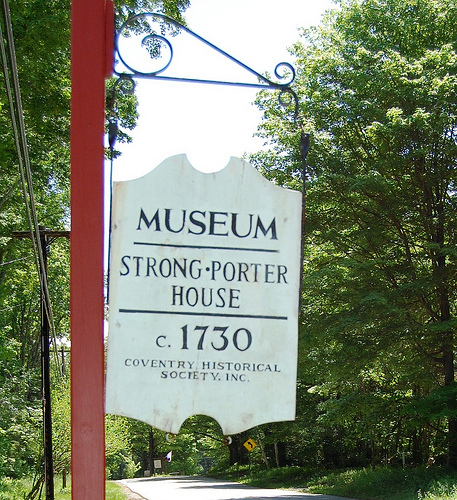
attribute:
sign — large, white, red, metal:
[110, 154, 305, 436]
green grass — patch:
[235, 451, 440, 498]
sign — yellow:
[244, 438, 258, 453]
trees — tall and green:
[257, 1, 455, 468]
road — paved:
[116, 468, 369, 498]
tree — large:
[303, 54, 456, 332]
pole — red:
[70, 1, 117, 495]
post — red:
[68, 4, 107, 498]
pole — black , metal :
[20, 225, 61, 463]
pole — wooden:
[3, 77, 53, 189]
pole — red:
[68, 1, 107, 498]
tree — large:
[304, 0, 456, 487]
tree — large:
[307, 178, 434, 471]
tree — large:
[124, 415, 172, 475]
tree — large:
[190, 430, 252, 475]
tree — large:
[34, 380, 131, 498]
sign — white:
[140, 171, 283, 407]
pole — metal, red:
[72, 0, 105, 498]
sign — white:
[84, 143, 307, 460]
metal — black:
[108, 54, 318, 177]